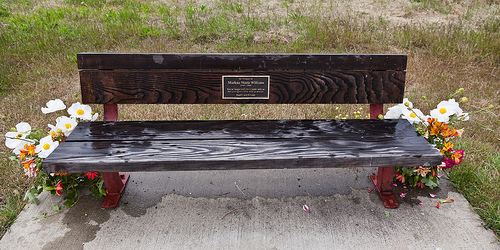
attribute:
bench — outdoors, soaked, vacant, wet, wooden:
[44, 47, 438, 220]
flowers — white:
[4, 95, 468, 191]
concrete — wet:
[36, 181, 467, 243]